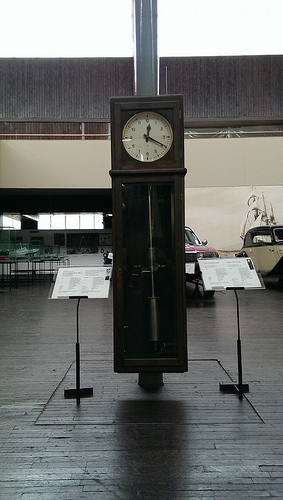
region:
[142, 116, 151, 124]
a number on a clock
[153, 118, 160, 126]
a number on a clock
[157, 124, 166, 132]
a number on a clock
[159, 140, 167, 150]
a number on a clock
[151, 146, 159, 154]
a number on a clock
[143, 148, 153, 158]
a number on a clock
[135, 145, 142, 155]
a number on a clock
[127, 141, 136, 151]
a number on a clock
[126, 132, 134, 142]
a number on a clock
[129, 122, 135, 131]
a number on a clock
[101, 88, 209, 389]
grandfather clock on display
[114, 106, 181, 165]
clock face that reads 12:20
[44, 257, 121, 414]
music stand with information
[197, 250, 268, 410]
music stand with grandfather clock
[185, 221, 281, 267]
classic collector vehicle on display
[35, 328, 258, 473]
square cut out of floor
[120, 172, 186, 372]
chiming mechanism of grandfather clock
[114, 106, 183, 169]
circular clock face with arabic numbers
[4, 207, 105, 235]
series of upper windows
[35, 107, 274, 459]
room with items on display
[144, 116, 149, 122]
a number on a clock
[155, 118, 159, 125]
a number on a clock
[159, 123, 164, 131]
a number on a clock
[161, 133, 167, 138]
a number on a clock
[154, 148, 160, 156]
a number on a clock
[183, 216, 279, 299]
Two cars are in the background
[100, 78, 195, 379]
A clock is in the foreground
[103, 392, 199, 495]
The clock is casting a shadow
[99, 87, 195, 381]
The clock's frame is made out of wood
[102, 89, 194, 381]
The clock's wood is dark colored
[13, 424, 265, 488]
The floor is hard wood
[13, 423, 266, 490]
The floor is dark colored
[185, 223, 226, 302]
Car in the background's body paint is red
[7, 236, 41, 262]
A model ship is in the background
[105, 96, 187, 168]
The clock's time is at 12:20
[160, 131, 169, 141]
a number on a clock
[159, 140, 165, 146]
a number on a clock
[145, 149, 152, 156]
a number on a clock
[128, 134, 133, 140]
a number on a clock